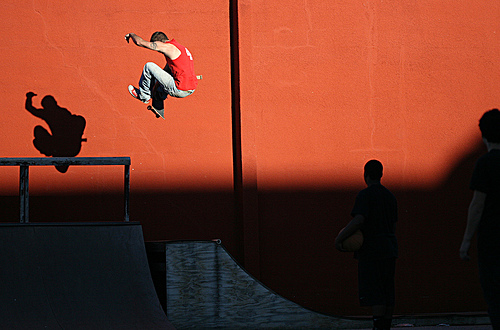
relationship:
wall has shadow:
[1, 8, 498, 309] [24, 92, 84, 171]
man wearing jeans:
[459, 108, 497, 328] [478, 229, 500, 323]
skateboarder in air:
[126, 31, 201, 120] [1, 0, 499, 321]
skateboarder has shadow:
[126, 31, 201, 120] [24, 92, 84, 171]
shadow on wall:
[24, 92, 84, 171] [1, 8, 498, 309]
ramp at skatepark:
[1, 225, 177, 329] [1, 3, 499, 326]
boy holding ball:
[335, 158, 401, 327] [338, 225, 364, 251]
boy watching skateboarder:
[335, 158, 401, 327] [126, 31, 201, 120]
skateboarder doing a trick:
[126, 31, 201, 120] [126, 31, 201, 120]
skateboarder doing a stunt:
[126, 31, 201, 120] [126, 31, 201, 120]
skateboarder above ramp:
[126, 31, 201, 120] [144, 236, 355, 329]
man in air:
[126, 31, 201, 120] [1, 0, 499, 321]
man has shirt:
[126, 31, 201, 120] [159, 40, 197, 91]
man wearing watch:
[126, 31, 201, 120] [125, 33, 131, 39]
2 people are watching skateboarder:
[338, 107, 497, 327] [126, 31, 201, 120]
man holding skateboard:
[126, 31, 201, 120] [149, 82, 166, 120]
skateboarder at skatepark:
[126, 31, 201, 120] [1, 3, 499, 326]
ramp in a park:
[1, 225, 177, 329] [1, 3, 499, 326]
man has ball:
[335, 158, 401, 327] [338, 225, 364, 251]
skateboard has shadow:
[126, 31, 201, 120] [24, 92, 84, 171]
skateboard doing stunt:
[149, 82, 166, 120] [126, 31, 201, 120]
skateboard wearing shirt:
[126, 31, 201, 120] [159, 40, 197, 91]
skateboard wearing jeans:
[126, 31, 201, 120] [135, 63, 194, 112]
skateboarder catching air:
[126, 31, 201, 120] [1, 0, 499, 321]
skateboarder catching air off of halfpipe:
[126, 31, 201, 120] [144, 236, 355, 329]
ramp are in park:
[1, 225, 177, 329] [1, 3, 499, 326]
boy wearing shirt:
[126, 31, 201, 120] [159, 40, 197, 91]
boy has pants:
[126, 31, 201, 120] [135, 63, 194, 112]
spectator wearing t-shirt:
[335, 158, 401, 327] [352, 186, 397, 256]